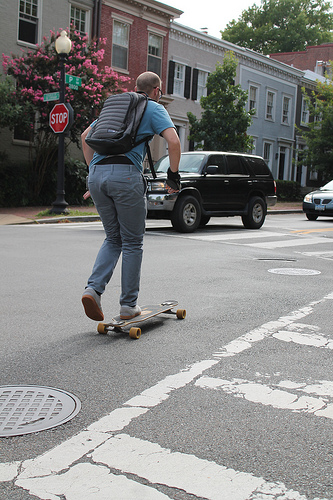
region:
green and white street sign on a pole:
[65, 74, 82, 90]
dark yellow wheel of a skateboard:
[128, 326, 142, 338]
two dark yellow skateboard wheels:
[127, 309, 189, 340]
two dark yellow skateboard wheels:
[95, 322, 142, 339]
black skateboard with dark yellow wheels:
[96, 298, 187, 338]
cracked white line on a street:
[192, 367, 331, 428]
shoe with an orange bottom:
[80, 286, 104, 321]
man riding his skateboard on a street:
[77, 70, 187, 340]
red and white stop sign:
[47, 102, 70, 133]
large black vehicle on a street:
[144, 149, 277, 234]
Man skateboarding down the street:
[81, 72, 186, 338]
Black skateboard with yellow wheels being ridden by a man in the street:
[97, 298, 186, 337]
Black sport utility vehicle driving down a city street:
[147, 151, 278, 228]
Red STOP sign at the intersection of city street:
[48, 103, 70, 134]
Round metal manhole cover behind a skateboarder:
[0, 380, 80, 435]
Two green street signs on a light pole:
[39, 70, 78, 99]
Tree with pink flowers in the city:
[2, 19, 128, 193]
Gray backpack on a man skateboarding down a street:
[88, 90, 152, 148]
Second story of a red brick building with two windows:
[97, 0, 166, 94]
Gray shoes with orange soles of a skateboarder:
[81, 286, 139, 319]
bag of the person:
[78, 83, 154, 175]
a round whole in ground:
[9, 385, 105, 450]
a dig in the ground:
[4, 364, 93, 434]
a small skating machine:
[93, 298, 202, 354]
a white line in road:
[69, 408, 251, 498]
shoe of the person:
[74, 290, 106, 322]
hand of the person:
[158, 136, 187, 180]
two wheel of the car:
[173, 189, 290, 238]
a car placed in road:
[132, 127, 302, 245]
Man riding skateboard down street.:
[76, 67, 193, 341]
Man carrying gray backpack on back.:
[82, 86, 152, 160]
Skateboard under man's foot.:
[95, 297, 192, 345]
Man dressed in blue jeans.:
[82, 163, 152, 307]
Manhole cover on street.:
[0, 377, 80, 442]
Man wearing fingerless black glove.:
[162, 166, 184, 191]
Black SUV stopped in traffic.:
[145, 145, 280, 236]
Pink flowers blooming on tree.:
[2, 22, 142, 211]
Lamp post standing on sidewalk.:
[41, 24, 84, 212]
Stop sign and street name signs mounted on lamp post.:
[40, 72, 87, 134]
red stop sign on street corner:
[48, 101, 68, 132]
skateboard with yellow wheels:
[94, 291, 188, 343]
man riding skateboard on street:
[80, 70, 182, 339]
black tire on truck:
[241, 192, 268, 231]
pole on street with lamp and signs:
[42, 29, 83, 219]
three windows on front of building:
[247, 81, 293, 128]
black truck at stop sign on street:
[147, 150, 279, 233]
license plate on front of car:
[315, 203, 325, 210]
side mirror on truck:
[202, 164, 219, 177]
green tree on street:
[184, 50, 249, 153]